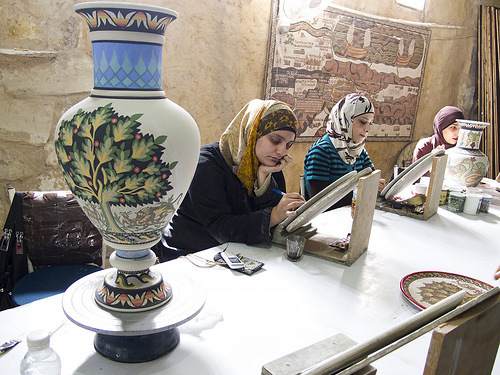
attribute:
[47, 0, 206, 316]
vase — large, featured, decorative, painted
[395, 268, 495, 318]
plate — decorative, painted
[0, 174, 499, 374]
table — long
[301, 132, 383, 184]
stripes — black, blue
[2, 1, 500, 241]
wall — brown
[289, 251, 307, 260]
liquid — dark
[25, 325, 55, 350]
cap — white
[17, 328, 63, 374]
water bottle — clear, plastic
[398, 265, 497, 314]
trim — red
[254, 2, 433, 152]
tapestry — hanging